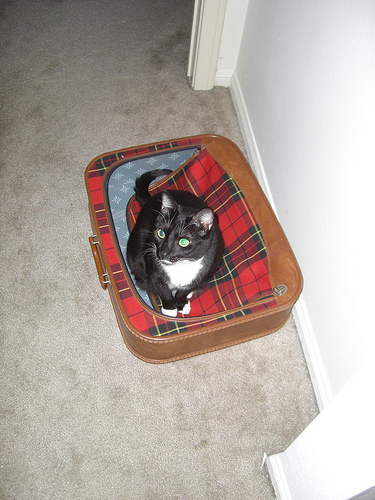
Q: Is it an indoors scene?
A: Yes, it is indoors.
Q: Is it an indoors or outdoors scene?
A: It is indoors.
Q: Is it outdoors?
A: No, it is indoors.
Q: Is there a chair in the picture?
A: No, there are no chairs.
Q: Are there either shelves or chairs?
A: No, there are no chairs or shelves.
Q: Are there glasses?
A: No, there are no glasses.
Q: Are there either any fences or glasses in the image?
A: No, there are no glasses or fences.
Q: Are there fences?
A: No, there are no fences.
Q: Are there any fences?
A: No, there are no fences.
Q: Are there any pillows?
A: No, there are no pillows.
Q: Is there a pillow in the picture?
A: No, there are no pillows.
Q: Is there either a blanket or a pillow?
A: No, there are no pillows or blankets.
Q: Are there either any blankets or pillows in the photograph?
A: No, there are no pillows or blankets.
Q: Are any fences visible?
A: No, there are no fences.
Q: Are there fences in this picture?
A: No, there are no fences.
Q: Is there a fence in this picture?
A: No, there are no fences.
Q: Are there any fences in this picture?
A: No, there are no fences.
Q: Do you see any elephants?
A: No, there are no elephants.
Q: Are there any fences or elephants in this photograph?
A: No, there are no elephants or fences.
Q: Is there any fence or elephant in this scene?
A: No, there are no elephants or fences.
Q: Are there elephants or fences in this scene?
A: No, there are no elephants or fences.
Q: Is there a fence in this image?
A: No, there are no fences.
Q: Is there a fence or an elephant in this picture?
A: No, there are no fences or elephants.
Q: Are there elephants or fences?
A: No, there are no fences or elephants.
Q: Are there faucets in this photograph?
A: No, there are no faucets.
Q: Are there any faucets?
A: No, there are no faucets.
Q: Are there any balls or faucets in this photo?
A: No, there are no faucets or balls.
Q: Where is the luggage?
A: The luggage is on the floor.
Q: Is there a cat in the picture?
A: Yes, there is a cat.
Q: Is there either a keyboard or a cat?
A: Yes, there is a cat.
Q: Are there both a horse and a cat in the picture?
A: No, there is a cat but no horses.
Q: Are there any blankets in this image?
A: No, there are no blankets.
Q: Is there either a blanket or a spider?
A: No, there are no blankets or spiders.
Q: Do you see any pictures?
A: No, there are no pictures.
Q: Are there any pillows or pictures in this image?
A: No, there are no pictures or pillows.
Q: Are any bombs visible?
A: No, there are no bombs.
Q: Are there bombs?
A: No, there are no bombs.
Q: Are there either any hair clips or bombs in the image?
A: No, there are no bombs or hair clips.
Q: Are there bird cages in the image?
A: No, there are no bird cages.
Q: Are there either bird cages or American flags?
A: No, there are no bird cages or American flags.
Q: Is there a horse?
A: No, there are no horses.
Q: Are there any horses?
A: No, there are no horses.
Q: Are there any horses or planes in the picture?
A: No, there are no horses or planes.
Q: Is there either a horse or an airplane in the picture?
A: No, there are no horses or airplanes.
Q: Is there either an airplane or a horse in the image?
A: No, there are no horses or airplanes.